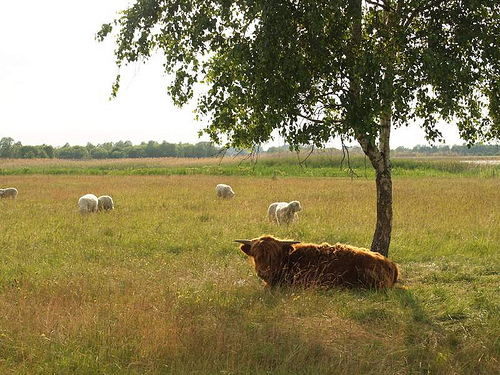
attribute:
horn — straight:
[234, 236, 251, 249]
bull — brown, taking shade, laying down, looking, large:
[239, 237, 399, 291]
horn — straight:
[278, 239, 299, 246]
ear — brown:
[282, 245, 296, 252]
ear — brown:
[240, 244, 259, 254]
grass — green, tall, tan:
[241, 285, 392, 330]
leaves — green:
[90, 1, 500, 149]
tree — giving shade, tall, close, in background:
[95, 1, 498, 289]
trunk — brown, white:
[347, 12, 391, 253]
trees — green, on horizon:
[2, 136, 498, 155]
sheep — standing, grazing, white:
[267, 201, 302, 225]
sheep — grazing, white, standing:
[214, 185, 238, 200]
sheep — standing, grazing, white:
[77, 194, 114, 211]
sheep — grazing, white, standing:
[0, 186, 18, 201]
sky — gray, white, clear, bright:
[13, 0, 477, 145]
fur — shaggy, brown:
[248, 241, 283, 256]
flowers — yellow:
[11, 287, 29, 304]